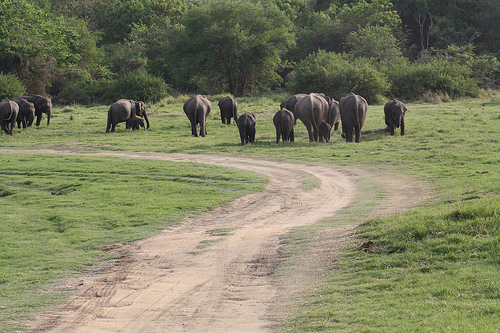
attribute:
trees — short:
[5, 4, 499, 105]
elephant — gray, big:
[334, 71, 371, 132]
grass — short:
[0, 154, 152, 241]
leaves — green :
[0, 0, 499, 108]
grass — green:
[10, 163, 186, 216]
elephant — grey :
[231, 101, 281, 157]